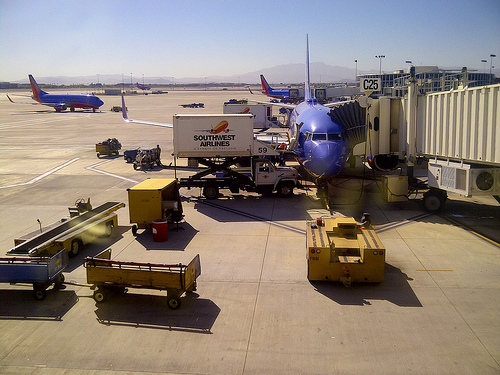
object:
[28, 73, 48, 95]
fin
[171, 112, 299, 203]
truck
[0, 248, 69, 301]
cart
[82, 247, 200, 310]
cart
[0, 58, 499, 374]
tarp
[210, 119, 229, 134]
plane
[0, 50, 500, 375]
airport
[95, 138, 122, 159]
cart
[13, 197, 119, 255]
cart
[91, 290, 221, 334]
shadow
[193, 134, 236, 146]
airline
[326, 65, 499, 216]
bridge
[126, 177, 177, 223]
yellow vest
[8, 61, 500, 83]
hills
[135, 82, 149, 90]
airplane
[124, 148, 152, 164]
carts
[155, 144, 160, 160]
person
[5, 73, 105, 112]
airplane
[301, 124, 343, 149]
cockpit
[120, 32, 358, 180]
airplane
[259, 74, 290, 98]
airplane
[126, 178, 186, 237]
cart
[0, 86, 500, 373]
pavement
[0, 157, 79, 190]
line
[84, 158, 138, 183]
line